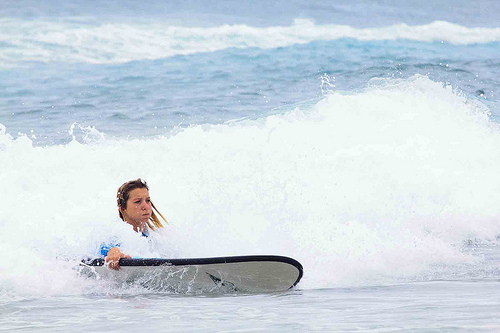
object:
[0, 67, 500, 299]
wave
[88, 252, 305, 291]
black ring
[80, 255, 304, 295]
surfboard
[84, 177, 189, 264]
woman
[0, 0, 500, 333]
photo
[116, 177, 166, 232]
hair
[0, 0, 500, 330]
water